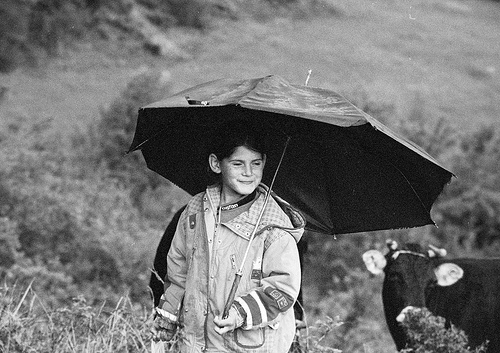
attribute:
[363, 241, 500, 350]
cow — black, dark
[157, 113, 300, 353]
girl — young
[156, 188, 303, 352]
jacket — rain jacket, rain coat, plaid design, white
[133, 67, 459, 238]
umbrella — black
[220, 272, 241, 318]
handle — wooden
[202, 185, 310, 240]
hood — plaid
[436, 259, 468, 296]
ear — white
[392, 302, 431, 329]
nose — white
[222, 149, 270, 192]
face expression — happy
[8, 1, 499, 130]
grass — tall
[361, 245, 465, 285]
ears — white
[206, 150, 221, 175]
ear — large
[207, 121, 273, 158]
hair — dark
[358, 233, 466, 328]
head — black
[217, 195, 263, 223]
shirt — gray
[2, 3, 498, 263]
field — grass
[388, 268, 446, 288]
eyes — open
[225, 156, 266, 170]
eyes — open